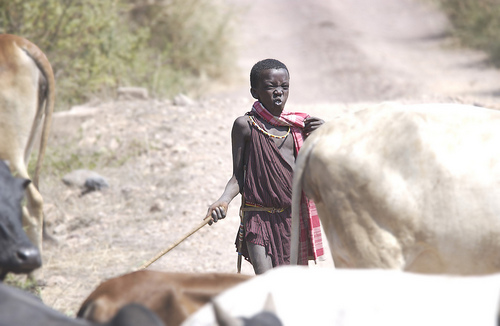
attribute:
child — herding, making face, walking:
[205, 55, 326, 271]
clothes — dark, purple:
[242, 115, 317, 261]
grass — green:
[0, 1, 228, 98]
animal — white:
[296, 101, 499, 280]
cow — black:
[0, 160, 89, 324]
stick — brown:
[133, 217, 214, 274]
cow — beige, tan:
[0, 33, 54, 179]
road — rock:
[45, 7, 499, 312]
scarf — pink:
[253, 102, 327, 256]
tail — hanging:
[282, 127, 323, 264]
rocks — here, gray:
[66, 163, 193, 238]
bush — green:
[2, 2, 209, 92]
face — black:
[0, 162, 44, 277]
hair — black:
[250, 58, 285, 77]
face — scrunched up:
[258, 71, 289, 104]